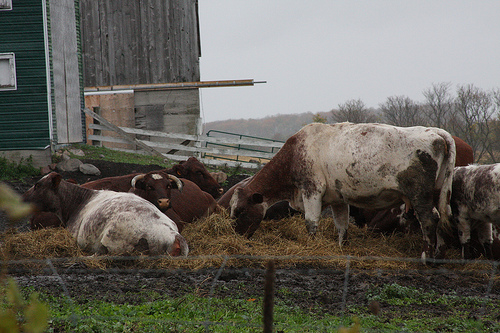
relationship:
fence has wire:
[0, 254, 500, 332] [0, 255, 499, 331]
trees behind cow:
[307, 83, 500, 164] [227, 121, 456, 265]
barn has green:
[0, 1, 201, 173] [0, 0, 86, 149]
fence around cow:
[84, 106, 287, 170] [227, 121, 456, 265]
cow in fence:
[227, 121, 456, 265] [84, 106, 287, 170]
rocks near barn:
[38, 147, 101, 176] [0, 1, 201, 173]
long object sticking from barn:
[82, 78, 268, 93] [0, 1, 201, 173]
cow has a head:
[227, 121, 456, 265] [228, 183, 269, 239]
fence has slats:
[84, 106, 287, 170] [82, 106, 285, 170]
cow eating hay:
[227, 121, 456, 265] [1, 203, 499, 280]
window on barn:
[0, 53, 18, 93] [0, 1, 201, 173]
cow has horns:
[128, 170, 228, 233] [131, 173, 184, 191]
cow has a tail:
[227, 121, 456, 265] [430, 126, 457, 244]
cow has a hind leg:
[227, 121, 456, 265] [403, 170, 437, 266]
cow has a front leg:
[227, 121, 456, 265] [301, 169, 327, 241]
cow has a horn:
[128, 170, 228, 233] [165, 172, 183, 191]